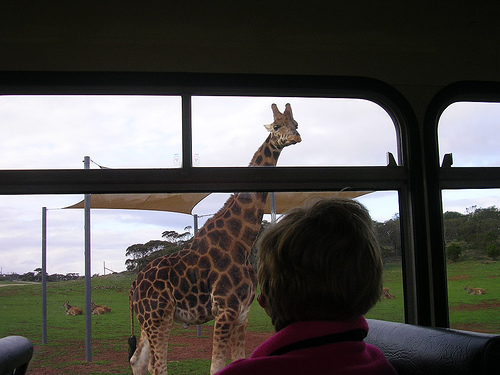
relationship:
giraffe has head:
[96, 99, 300, 375] [261, 99, 309, 152]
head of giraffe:
[261, 99, 309, 152] [96, 99, 300, 375]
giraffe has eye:
[96, 99, 300, 375] [271, 121, 282, 133]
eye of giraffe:
[271, 121, 282, 133] [96, 99, 300, 375]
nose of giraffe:
[296, 131, 302, 138] [96, 99, 300, 375]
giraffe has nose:
[96, 99, 300, 375] [296, 131, 302, 138]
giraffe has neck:
[96, 99, 300, 375] [229, 145, 271, 234]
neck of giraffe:
[229, 145, 271, 234] [96, 99, 300, 375]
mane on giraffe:
[204, 146, 255, 228] [96, 99, 300, 375]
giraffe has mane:
[96, 99, 300, 375] [204, 146, 255, 228]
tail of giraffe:
[125, 333, 140, 361] [96, 99, 300, 375]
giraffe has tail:
[96, 99, 300, 375] [125, 333, 140, 361]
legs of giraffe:
[130, 315, 240, 373] [96, 99, 300, 375]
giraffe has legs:
[96, 99, 300, 375] [130, 315, 240, 373]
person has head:
[233, 194, 396, 372] [251, 192, 386, 324]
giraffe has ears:
[96, 99, 300, 375] [263, 103, 301, 116]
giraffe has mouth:
[96, 99, 300, 375] [292, 140, 302, 144]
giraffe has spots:
[96, 99, 300, 375] [175, 259, 217, 276]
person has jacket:
[233, 194, 396, 372] [186, 333, 421, 373]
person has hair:
[233, 194, 396, 372] [285, 231, 343, 275]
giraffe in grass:
[96, 99, 300, 375] [25, 310, 123, 343]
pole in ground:
[33, 205, 60, 351] [42, 340, 82, 368]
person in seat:
[233, 194, 396, 372] [389, 325, 499, 374]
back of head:
[290, 249, 344, 304] [261, 99, 309, 152]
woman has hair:
[233, 194, 396, 372] [285, 231, 343, 275]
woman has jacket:
[233, 194, 396, 372] [186, 333, 421, 373]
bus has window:
[7, 59, 497, 374] [10, 97, 170, 162]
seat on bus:
[389, 325, 499, 374] [7, 59, 497, 374]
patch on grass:
[54, 344, 82, 371] [25, 310, 123, 343]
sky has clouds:
[33, 107, 461, 144] [67, 107, 125, 125]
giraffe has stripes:
[96, 99, 300, 375] [142, 331, 166, 362]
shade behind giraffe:
[88, 198, 205, 216] [96, 99, 300, 375]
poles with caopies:
[32, 211, 121, 373] [88, 198, 205, 216]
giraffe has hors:
[96, 99, 300, 375] [267, 103, 297, 109]